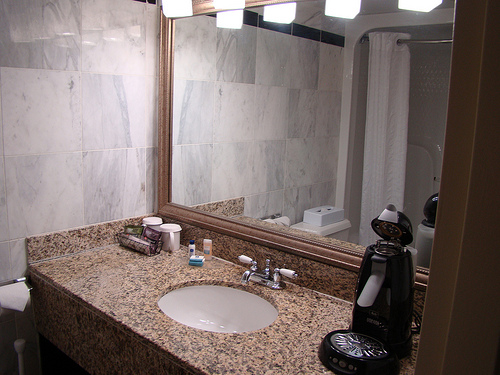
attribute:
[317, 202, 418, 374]
coffee maker — coffee maker, black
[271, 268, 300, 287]
handle — white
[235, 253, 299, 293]
faucet — silver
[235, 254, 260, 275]
handle — white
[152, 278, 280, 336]
sink — white, one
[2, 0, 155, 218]
wall — marble, gray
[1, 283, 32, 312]
toilet paper — roll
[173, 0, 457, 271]
mirror — reflecting, mounted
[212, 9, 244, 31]
light — reflected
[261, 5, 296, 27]
light — reflected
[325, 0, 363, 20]
light — reflected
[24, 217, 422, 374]
counter — granite, brown, marble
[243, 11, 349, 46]
strip — black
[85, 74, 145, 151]
tile — marble, white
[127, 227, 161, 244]
soaps — complimentary, group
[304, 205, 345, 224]
box — white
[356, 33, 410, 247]
curtains — white